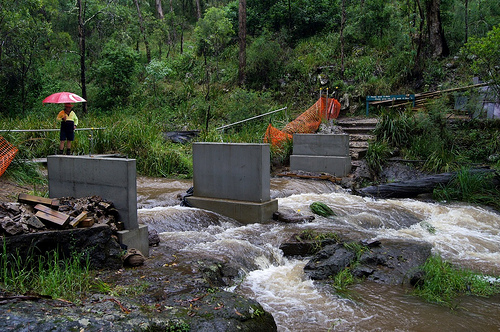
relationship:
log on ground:
[380, 169, 444, 198] [377, 145, 460, 173]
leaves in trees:
[221, 68, 225, 72] [32, 27, 336, 119]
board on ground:
[3, 190, 118, 240] [1, 252, 247, 325]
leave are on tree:
[403, 33, 405, 35] [230, 0, 256, 92]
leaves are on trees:
[221, 68, 225, 72] [178, 23, 292, 100]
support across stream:
[291, 133, 356, 176] [93, 154, 498, 327]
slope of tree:
[2, 4, 473, 152] [234, 1, 249, 84]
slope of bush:
[2, 4, 473, 152] [448, 31, 498, 81]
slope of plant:
[2, 4, 473, 152] [115, 117, 159, 160]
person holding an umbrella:
[47, 103, 83, 157] [34, 86, 88, 110]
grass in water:
[408, 251, 481, 307] [34, 167, 484, 326]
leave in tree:
[377, 35, 413, 65] [6, 0, 468, 180]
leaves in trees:
[289, 40, 399, 88] [6, 3, 480, 198]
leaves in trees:
[221, 68, 225, 72] [3, 1, 498, 111]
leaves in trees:
[177, 60, 241, 93] [193, 2, 255, 126]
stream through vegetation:
[5, 164, 484, 327] [128, 23, 250, 98]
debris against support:
[3, 178, 140, 254] [47, 152, 147, 249]